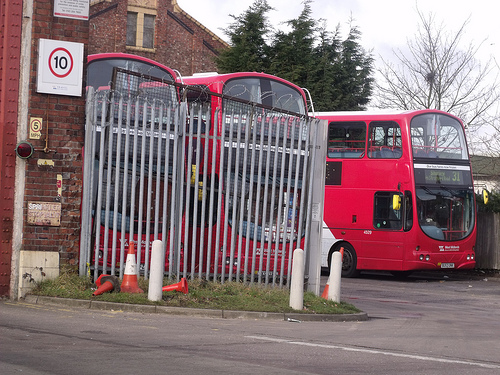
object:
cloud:
[371, 0, 500, 79]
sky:
[178, 0, 500, 156]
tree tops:
[215, 0, 377, 110]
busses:
[84, 52, 479, 278]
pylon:
[120, 241, 146, 294]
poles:
[78, 84, 193, 301]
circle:
[47, 46, 74, 78]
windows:
[409, 112, 475, 242]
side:
[316, 111, 417, 277]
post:
[328, 251, 343, 303]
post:
[289, 247, 306, 310]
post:
[148, 240, 166, 302]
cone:
[120, 242, 144, 294]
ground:
[2, 273, 500, 375]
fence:
[78, 67, 328, 284]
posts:
[79, 85, 94, 282]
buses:
[80, 51, 317, 282]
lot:
[7, 270, 497, 375]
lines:
[242, 332, 498, 371]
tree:
[212, 0, 375, 116]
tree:
[371, 0, 499, 154]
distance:
[2, 0, 497, 175]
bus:
[146, 108, 479, 278]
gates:
[77, 83, 328, 279]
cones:
[92, 241, 188, 299]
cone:
[320, 246, 344, 303]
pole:
[306, 118, 329, 295]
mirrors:
[391, 187, 489, 212]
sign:
[29, 117, 43, 140]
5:
[33, 121, 38, 129]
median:
[25, 239, 368, 322]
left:
[4, 2, 262, 375]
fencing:
[78, 65, 327, 296]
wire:
[104, 60, 316, 127]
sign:
[423, 169, 465, 185]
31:
[452, 171, 460, 181]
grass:
[29, 267, 361, 313]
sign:
[35, 37, 85, 98]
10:
[53, 55, 68, 69]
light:
[14, 140, 34, 159]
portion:
[472, 193, 499, 270]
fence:
[469, 186, 499, 272]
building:
[0, 0, 237, 291]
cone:
[92, 273, 121, 296]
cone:
[162, 278, 189, 295]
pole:
[289, 249, 306, 311]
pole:
[327, 251, 342, 304]